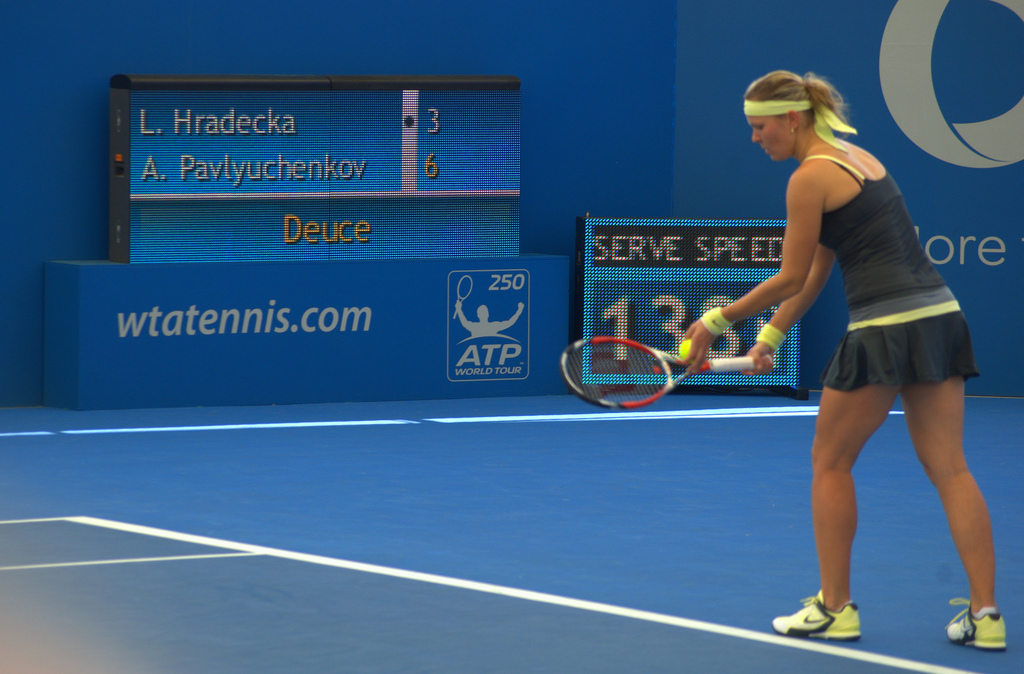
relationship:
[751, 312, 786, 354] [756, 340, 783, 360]
headband on wrist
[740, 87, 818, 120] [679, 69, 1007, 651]
headband on player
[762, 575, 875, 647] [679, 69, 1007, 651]
sneaker on player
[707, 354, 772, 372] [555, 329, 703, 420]
racket handle on racket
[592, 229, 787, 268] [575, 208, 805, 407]
word on sign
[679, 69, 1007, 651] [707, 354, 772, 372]
player holding racket handle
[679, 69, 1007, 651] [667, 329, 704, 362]
player holding ball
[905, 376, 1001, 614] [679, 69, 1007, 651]
leg on player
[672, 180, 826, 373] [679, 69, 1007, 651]
arm on player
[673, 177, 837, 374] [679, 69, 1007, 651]
arm on player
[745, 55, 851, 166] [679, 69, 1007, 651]
head on player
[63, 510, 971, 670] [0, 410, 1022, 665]
line on tennis court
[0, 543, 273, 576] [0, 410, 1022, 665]
line on tennis court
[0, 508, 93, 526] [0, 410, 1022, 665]
line on tennis court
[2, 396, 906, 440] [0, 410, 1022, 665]
line on tennis court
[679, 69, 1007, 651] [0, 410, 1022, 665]
player on tennis court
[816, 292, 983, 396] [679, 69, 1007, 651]
skirt on player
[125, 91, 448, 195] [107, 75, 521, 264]
score on sign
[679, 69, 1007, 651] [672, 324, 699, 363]
player looking at ball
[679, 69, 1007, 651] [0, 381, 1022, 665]
player on tennis court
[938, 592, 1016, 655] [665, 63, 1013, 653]
shoe on player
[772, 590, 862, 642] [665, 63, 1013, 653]
sneaker on player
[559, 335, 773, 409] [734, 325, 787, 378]
racket in hand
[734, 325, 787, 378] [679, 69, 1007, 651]
hand on player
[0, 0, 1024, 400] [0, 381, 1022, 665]
wall near tennis court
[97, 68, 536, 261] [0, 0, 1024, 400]
sign on wall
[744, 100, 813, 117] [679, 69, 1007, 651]
headband on player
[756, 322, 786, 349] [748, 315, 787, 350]
headband on wrist